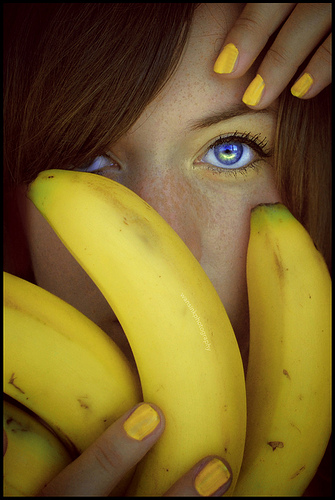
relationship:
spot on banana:
[267, 438, 289, 455] [245, 206, 322, 499]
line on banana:
[269, 246, 294, 292] [245, 206, 322, 499]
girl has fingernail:
[10, 13, 333, 331] [209, 52, 232, 81]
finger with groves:
[224, 0, 268, 72] [231, 11, 264, 37]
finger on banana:
[27, 397, 154, 496] [245, 206, 322, 499]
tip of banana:
[252, 199, 288, 216] [245, 206, 322, 499]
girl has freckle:
[10, 13, 333, 331] [183, 190, 206, 207]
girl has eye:
[10, 13, 333, 331] [200, 147, 266, 172]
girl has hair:
[10, 13, 333, 331] [5, 6, 334, 259]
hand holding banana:
[37, 404, 255, 499] [245, 206, 322, 499]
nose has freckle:
[135, 170, 208, 260] [183, 190, 206, 207]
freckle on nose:
[183, 190, 206, 207] [135, 170, 208, 260]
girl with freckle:
[0, 13, 333, 493] [183, 190, 206, 207]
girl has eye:
[0, 13, 333, 493] [200, 147, 266, 172]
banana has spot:
[245, 206, 322, 499] [267, 438, 289, 455]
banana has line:
[245, 206, 322, 499] [269, 246, 294, 292]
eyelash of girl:
[212, 133, 271, 161] [0, 13, 333, 493]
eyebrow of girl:
[189, 97, 282, 125] [0, 13, 333, 493]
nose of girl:
[135, 170, 208, 260] [0, 13, 333, 493]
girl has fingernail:
[0, 13, 333, 493] [209, 52, 232, 81]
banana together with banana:
[245, 206, 322, 499] [37, 179, 236, 499]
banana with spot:
[245, 206, 322, 499] [267, 438, 289, 455]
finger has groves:
[224, 0, 268, 72] [231, 11, 264, 37]